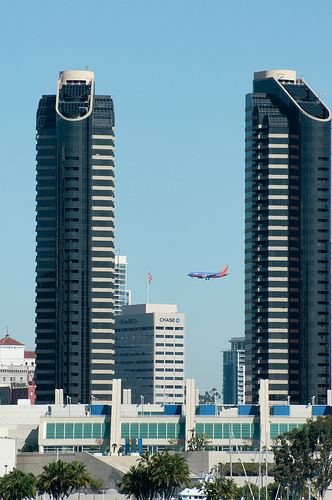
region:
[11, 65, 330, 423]
a Southwest airliner seen in the distance between two tall buildings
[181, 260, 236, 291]
blue and orange Southwest jetliner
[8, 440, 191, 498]
several bunches of palm trees on the ground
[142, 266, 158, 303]
a flag on the top of a bank building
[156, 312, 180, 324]
the Chase logo on a tall building in the city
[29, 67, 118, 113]
the penthouse area of a very tall building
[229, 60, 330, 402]
a very tall skyscraper in a big city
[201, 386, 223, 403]
a bunch of tall trees in the far distance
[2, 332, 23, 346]
a red roof of a building in the distance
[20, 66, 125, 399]
a very tall skyscraper in a big city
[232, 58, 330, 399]
a big tower on the right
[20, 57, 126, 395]
a tower big building on the left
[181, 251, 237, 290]
a plane flying in the sky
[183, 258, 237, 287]
plane is blue and red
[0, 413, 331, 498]
several trees in front of buildings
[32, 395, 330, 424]
roof of a building has blue spots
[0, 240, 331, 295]
plane flying in middle of two two buildings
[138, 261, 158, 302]
a flag on the top of building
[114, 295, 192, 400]
a building that says CHASE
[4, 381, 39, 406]
a building that si red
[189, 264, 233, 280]
blue plane with red wing tip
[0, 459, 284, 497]
palm trees in foreground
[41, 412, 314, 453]
white building with green windows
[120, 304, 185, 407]
Chase Bank logo on light gray building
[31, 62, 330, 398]
two twin skyscrapers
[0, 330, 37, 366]
white building with red roof in background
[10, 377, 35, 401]
red brick building in background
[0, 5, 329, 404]
clear, blue, sunny sky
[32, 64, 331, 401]
dark gray skyscrapers with white roofs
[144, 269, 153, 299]
American flag atop Chase building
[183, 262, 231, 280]
blue and red jet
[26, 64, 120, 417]
skyscraper across from an identical skyscraper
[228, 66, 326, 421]
skyscraper across from an identical skyscraper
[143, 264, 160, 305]
national flag on top of building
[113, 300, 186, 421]
white bank building between two larger skyscrapers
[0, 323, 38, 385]
white and gray building with a red roof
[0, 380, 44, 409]
red brick building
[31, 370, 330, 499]
long white gray and blue building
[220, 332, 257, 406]
building behind skyscraper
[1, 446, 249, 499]
row of green palm trees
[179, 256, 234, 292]
plane in the sky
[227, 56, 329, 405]
large building on right side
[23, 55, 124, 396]
large building on the left side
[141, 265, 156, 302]
the flag is over a building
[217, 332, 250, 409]
building behind a building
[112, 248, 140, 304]
a building behind a CHASE building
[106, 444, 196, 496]
trees in front of a building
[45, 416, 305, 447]
top of a roof is green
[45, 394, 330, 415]
roof of a buildings has blue parts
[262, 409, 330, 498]
a big tree on the right